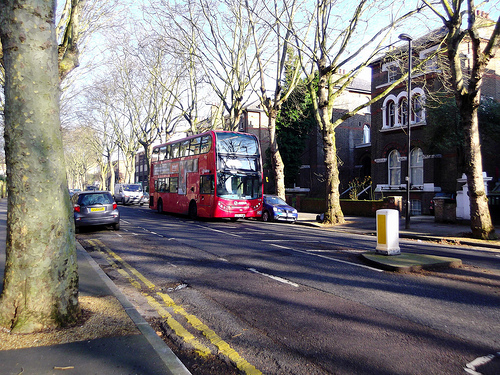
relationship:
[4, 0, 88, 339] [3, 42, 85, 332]
tree has trunk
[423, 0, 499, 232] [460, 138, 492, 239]
tree has trunk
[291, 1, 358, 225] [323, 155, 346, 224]
tree has trunk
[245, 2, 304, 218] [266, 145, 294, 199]
tree has trunk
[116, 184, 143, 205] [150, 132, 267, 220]
suv behind bus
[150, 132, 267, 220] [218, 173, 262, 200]
bus has windshield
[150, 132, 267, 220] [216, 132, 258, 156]
bus has windshield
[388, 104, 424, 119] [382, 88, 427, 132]
windows have trim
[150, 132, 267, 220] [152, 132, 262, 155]
bus has top deck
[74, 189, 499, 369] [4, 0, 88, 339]
street has tree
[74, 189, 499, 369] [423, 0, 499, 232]
street has tree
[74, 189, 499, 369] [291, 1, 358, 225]
street has tree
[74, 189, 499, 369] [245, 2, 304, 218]
street has tree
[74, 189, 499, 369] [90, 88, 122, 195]
street has tree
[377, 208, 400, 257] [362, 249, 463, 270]
pole in ground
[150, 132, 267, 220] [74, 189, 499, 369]
bus on street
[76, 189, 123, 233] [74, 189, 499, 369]
car on street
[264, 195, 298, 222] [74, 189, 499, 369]
car on street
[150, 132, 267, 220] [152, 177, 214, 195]
bus has lower level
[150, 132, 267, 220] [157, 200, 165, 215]
bus has tires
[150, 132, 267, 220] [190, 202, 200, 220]
bus has tires